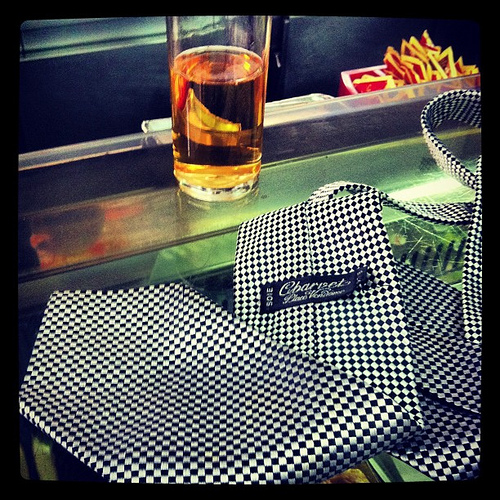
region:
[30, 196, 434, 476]
a black and white checkered tie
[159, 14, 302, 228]
beverage in the glass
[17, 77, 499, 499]
Black and white checkered tie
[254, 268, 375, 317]
Black tag on back of tie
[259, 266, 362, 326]
White lettering on tag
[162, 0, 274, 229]
Clear glass of brown liquid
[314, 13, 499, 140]
Red and white box in the background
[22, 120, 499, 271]
Skinny clear glass shelf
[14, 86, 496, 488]
Tie laying on glass shelf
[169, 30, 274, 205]
Tea in glass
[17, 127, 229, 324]
Reflection in glass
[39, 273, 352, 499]
Black and white diamonds on tie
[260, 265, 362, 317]
writing on the tie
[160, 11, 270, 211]
a glass on a shelf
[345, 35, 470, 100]
packets in a container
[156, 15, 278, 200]
a drink in the glass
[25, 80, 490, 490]
a black and white tie on a green glass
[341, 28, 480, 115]
yellow and red packets in a container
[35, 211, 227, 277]
a reflection in the glass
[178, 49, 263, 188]
a reflection in the glass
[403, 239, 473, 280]
black writing on the table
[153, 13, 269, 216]
glass that is half filled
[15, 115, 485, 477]
black and white checkered tie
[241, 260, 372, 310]
tag on the tie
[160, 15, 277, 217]
clear glass sitting on the counter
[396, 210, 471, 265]
scratches on the glass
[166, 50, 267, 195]
gold liquid in the glass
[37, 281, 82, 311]
tip of the tie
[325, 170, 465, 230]
skinny part of the tie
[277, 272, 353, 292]
white writing on the tag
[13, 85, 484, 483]
tie laying on the counter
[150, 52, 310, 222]
a white glass in table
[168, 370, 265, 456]
small desing on cloth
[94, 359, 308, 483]
black and white design in table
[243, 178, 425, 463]
a long neck tie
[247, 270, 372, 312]
name of the tie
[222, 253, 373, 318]
a black tag on tie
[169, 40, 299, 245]
a glass with wine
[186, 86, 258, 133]
a small shadow in glass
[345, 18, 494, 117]
a red hot box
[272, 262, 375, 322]
white text in black tag